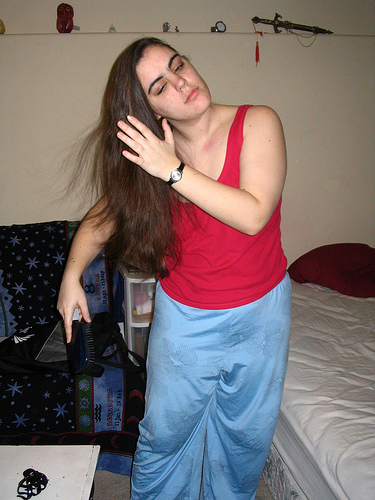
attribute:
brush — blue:
[68, 312, 102, 378]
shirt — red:
[189, 234, 247, 286]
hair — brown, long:
[105, 73, 124, 99]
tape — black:
[15, 466, 48, 500]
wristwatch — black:
[162, 163, 188, 184]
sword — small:
[237, 12, 353, 51]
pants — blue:
[130, 283, 296, 499]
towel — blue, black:
[6, 298, 14, 334]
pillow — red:
[309, 248, 357, 276]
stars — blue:
[20, 248, 47, 289]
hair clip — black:
[27, 470, 45, 482]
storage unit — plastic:
[128, 275, 155, 324]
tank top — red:
[226, 245, 263, 270]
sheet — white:
[313, 343, 367, 398]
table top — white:
[58, 449, 87, 476]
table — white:
[63, 443, 88, 485]